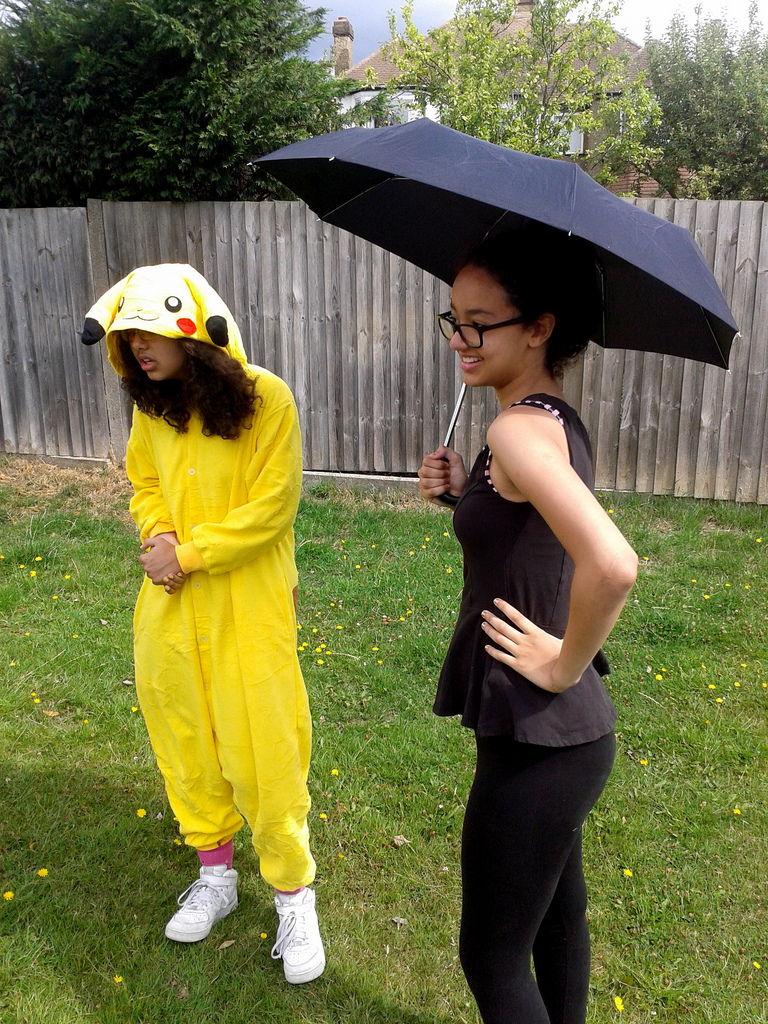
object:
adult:
[82, 258, 328, 987]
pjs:
[77, 263, 316, 890]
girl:
[419, 260, 638, 1024]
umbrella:
[247, 117, 754, 372]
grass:
[2, 458, 768, 1022]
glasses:
[438, 310, 538, 349]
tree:
[0, 2, 388, 207]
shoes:
[271, 887, 328, 985]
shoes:
[164, 865, 238, 944]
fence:
[2, 200, 768, 502]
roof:
[326, 6, 652, 96]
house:
[334, 3, 698, 198]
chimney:
[333, 16, 355, 77]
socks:
[196, 841, 231, 863]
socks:
[276, 885, 306, 894]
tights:
[456, 729, 616, 1022]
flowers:
[137, 810, 146, 819]